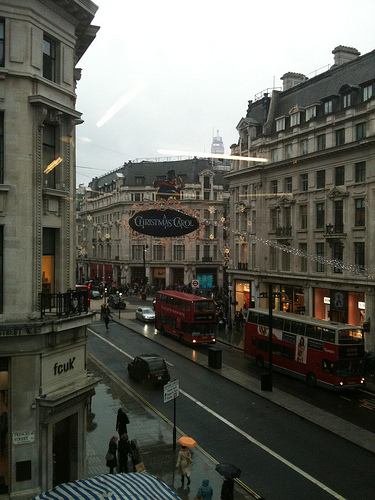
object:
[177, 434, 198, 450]
umbrella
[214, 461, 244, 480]
umbrella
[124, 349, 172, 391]
car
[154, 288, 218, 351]
bus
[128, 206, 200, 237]
sign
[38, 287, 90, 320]
railing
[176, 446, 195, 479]
coat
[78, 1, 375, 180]
sky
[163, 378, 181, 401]
sign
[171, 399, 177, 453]
post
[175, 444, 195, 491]
woman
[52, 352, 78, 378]
sign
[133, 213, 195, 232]
christmas carol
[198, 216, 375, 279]
strands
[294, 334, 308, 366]
advertisement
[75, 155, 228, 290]
building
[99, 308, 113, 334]
people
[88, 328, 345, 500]
line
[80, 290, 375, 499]
street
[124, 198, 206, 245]
decorations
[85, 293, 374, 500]
island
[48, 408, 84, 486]
doorway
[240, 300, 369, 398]
buses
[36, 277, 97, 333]
terrace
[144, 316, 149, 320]
headlights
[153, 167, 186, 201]
image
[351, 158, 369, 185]
windows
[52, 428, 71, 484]
door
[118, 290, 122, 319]
light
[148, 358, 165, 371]
window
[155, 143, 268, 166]
lights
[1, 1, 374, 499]
glass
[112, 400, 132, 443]
people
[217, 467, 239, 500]
person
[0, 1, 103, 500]
buildings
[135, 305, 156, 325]
vehicle